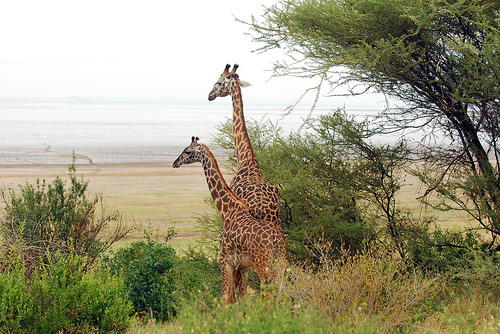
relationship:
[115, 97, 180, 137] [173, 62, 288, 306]
water in front of giraffes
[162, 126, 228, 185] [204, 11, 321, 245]
head of animal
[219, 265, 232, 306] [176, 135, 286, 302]
leg of animal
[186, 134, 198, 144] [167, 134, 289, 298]
horns on giraffe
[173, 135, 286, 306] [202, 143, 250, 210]
animal has mane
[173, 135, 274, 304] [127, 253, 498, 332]
animal on grass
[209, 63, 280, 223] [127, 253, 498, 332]
animal on grass